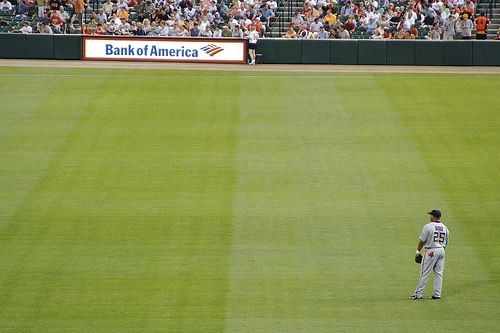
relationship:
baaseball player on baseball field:
[409, 207, 448, 299] [0, 65, 499, 329]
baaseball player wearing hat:
[409, 207, 448, 299] [427, 207, 444, 221]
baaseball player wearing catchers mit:
[409, 207, 448, 299] [411, 250, 429, 263]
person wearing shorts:
[244, 22, 263, 68] [246, 41, 258, 51]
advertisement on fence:
[77, 37, 244, 64] [0, 34, 498, 75]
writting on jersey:
[434, 224, 447, 245] [421, 220, 451, 252]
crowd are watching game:
[5, 1, 494, 40] [0, 69, 499, 331]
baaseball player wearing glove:
[409, 207, 448, 299] [405, 241, 459, 266]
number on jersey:
[431, 230, 446, 245] [418, 220, 452, 250]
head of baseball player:
[425, 208, 444, 223] [409, 206, 451, 303]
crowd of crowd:
[5, 1, 494, 40] [5, 1, 494, 40]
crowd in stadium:
[5, 1, 494, 40] [2, 1, 499, 61]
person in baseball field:
[244, 22, 263, 68] [1, 73, 496, 331]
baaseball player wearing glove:
[409, 207, 448, 299] [412, 251, 424, 265]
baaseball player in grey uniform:
[409, 207, 448, 299] [416, 221, 451, 296]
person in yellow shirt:
[321, 6, 337, 26] [322, 12, 337, 24]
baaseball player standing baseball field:
[409, 207, 448, 299] [0, 65, 499, 329]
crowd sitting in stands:
[232, 0, 486, 50] [5, 1, 479, 40]